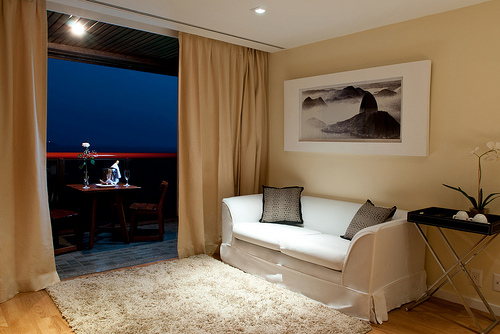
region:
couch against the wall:
[216, 167, 428, 313]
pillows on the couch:
[258, 165, 387, 246]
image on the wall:
[271, 63, 438, 161]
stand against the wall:
[406, 187, 498, 326]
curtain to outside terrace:
[136, 26, 279, 256]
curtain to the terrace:
[1, 4, 58, 319]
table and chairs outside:
[42, 157, 181, 254]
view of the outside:
[50, 73, 172, 145]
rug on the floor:
[47, 250, 374, 332]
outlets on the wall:
[471, 266, 499, 291]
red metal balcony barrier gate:
[47, 148, 180, 240]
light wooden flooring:
[1, 251, 499, 331]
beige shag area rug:
[44, 251, 372, 332]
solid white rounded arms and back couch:
[219, 190, 431, 322]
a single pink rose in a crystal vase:
[75, 138, 100, 186]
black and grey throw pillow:
[258, 182, 305, 225]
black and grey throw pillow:
[340, 197, 397, 240]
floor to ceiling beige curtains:
[176, 30, 272, 258]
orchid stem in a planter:
[440, 138, 499, 218]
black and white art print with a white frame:
[281, 59, 432, 156]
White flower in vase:
[75, 139, 98, 190]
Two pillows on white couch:
[217, 182, 431, 327]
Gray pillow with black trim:
[257, 181, 307, 228]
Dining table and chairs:
[45, 168, 175, 259]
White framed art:
[277, 57, 447, 161]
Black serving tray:
[404, 196, 499, 333]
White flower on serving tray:
[401, 139, 498, 331]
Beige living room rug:
[32, 249, 373, 333]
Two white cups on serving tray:
[402, 196, 498, 333]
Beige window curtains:
[0, 1, 275, 301]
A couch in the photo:
[215, 188, 436, 299]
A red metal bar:
[57, 139, 164, 161]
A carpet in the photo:
[100, 263, 230, 321]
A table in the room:
[76, 166, 147, 199]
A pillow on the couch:
[251, 173, 316, 223]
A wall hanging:
[291, 66, 432, 151]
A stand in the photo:
[400, 189, 498, 284]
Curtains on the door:
[12, 116, 41, 240]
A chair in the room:
[140, 182, 169, 240]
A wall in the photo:
[467, 37, 497, 144]